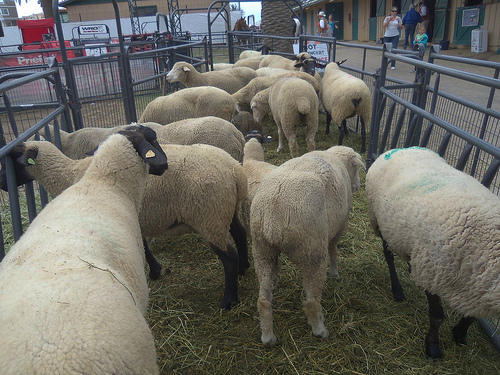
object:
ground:
[0, 42, 499, 373]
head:
[98, 123, 170, 181]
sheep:
[249, 77, 321, 156]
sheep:
[320, 62, 372, 155]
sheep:
[160, 61, 258, 92]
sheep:
[247, 143, 365, 350]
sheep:
[2, 123, 170, 374]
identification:
[145, 149, 160, 161]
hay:
[141, 258, 479, 375]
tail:
[292, 99, 311, 115]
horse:
[230, 17, 251, 44]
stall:
[350, 4, 360, 39]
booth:
[0, 16, 74, 67]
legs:
[335, 121, 343, 148]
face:
[165, 61, 188, 83]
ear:
[135, 138, 168, 169]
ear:
[181, 62, 192, 74]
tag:
[25, 154, 36, 166]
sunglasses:
[390, 9, 400, 13]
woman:
[381, 8, 402, 73]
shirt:
[411, 34, 427, 48]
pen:
[0, 0, 498, 369]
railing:
[230, 27, 499, 214]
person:
[314, 10, 334, 48]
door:
[368, 15, 380, 40]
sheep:
[0, 143, 248, 313]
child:
[410, 18, 431, 60]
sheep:
[291, 57, 326, 75]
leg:
[301, 256, 329, 337]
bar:
[122, 39, 199, 56]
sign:
[13, 54, 65, 70]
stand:
[471, 26, 489, 55]